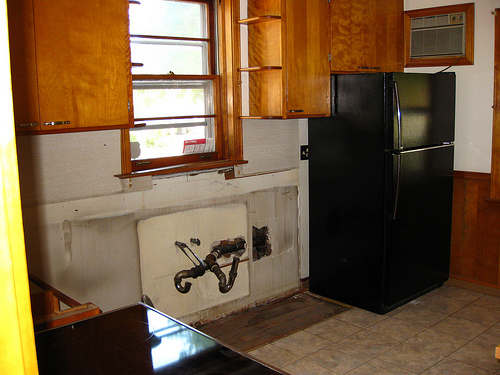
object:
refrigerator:
[306, 69, 459, 313]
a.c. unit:
[408, 13, 468, 60]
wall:
[454, 1, 496, 177]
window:
[126, 2, 229, 173]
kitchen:
[10, 5, 496, 372]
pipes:
[175, 237, 249, 294]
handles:
[386, 80, 402, 222]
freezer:
[380, 74, 461, 149]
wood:
[451, 176, 497, 290]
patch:
[189, 290, 352, 353]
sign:
[181, 138, 212, 153]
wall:
[17, 115, 306, 328]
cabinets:
[239, 2, 407, 117]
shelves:
[231, 0, 284, 117]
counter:
[35, 299, 285, 374]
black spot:
[73, 209, 80, 213]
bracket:
[123, 101, 135, 116]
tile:
[425, 290, 469, 317]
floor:
[285, 313, 500, 374]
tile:
[296, 307, 342, 336]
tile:
[275, 328, 329, 357]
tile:
[374, 338, 447, 369]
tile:
[306, 343, 375, 370]